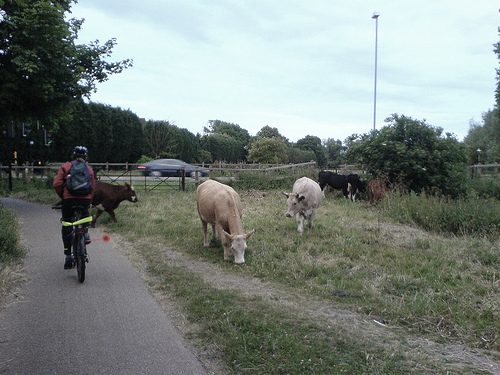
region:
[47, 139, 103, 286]
bicycle rider with helmet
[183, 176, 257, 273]
small cow eating grass on the side of a road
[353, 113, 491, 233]
green foliage near the side of a road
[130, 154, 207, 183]
dark gray car behind a fence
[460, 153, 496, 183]
small house in the background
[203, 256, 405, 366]
worn path in the grass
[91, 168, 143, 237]
brown cow with white markings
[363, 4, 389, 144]
tall gray pole with light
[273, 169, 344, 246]
cow walking in taller grass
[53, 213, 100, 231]
yellow safety reflection mark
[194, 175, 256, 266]
Tan cow grazing on grass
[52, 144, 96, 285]
Person with a backpack riding a bicycle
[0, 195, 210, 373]
Concrete biking path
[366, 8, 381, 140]
Tall pole with security light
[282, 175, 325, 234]
Standing white cow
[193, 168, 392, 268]
Cows grazing on grass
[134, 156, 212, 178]
Sedan driving on a road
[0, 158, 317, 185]
Short wooden fence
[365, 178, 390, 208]
Back end of a brown cow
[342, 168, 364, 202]
Back end of a black and white cow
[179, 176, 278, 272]
The cow is grazing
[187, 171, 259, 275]
The cow is tan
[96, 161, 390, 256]
A herd of cows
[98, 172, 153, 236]
The cow is white and brown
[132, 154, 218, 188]
A blue car on the street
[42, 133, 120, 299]
A person is biking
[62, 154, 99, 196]
The backpack is blue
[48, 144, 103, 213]
The person is wearing a red jacket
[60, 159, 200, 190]
The gate is black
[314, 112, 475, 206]
The cows are near a large bush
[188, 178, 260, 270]
tan cow grazing by road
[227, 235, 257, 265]
white face of cow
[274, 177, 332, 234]
cow looking at biker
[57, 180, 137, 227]
dark cow crossing road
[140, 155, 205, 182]
car on road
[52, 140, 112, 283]
biker on path by cow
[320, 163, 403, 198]
cows near a tree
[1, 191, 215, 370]
path for bikes by cows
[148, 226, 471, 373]
path in grass for cows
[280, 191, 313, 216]
white head of cow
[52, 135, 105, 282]
a cyclist passing in front a farm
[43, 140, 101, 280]
person rides a bike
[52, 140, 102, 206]
cyclist carry a backpack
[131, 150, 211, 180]
a black car running to the left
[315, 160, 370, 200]
a black cow nears a tree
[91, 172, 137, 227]
a cow crossing a road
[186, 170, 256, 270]
a brown cow eating grass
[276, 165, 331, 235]
a white cow on a field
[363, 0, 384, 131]
a light pole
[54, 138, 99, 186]
cyclist wears a black helmet